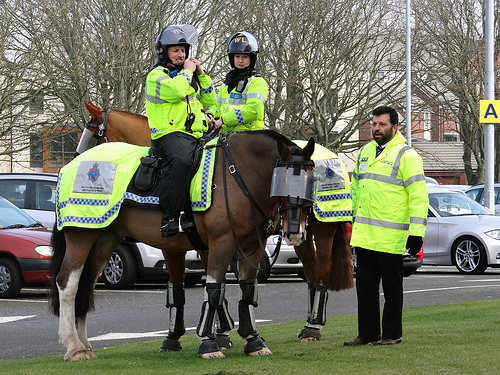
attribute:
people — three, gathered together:
[139, 22, 441, 364]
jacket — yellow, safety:
[136, 63, 221, 148]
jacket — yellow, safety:
[212, 67, 275, 129]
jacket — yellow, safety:
[343, 138, 437, 262]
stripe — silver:
[150, 72, 169, 100]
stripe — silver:
[234, 108, 247, 122]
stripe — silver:
[360, 167, 407, 189]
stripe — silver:
[358, 203, 414, 233]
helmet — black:
[223, 26, 258, 58]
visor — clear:
[159, 22, 198, 43]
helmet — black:
[152, 22, 191, 48]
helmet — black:
[223, 27, 261, 53]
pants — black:
[155, 135, 204, 212]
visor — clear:
[72, 124, 111, 153]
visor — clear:
[268, 163, 320, 203]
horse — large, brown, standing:
[43, 131, 317, 360]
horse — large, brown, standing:
[56, 96, 156, 156]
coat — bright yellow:
[141, 60, 202, 139]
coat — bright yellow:
[347, 141, 430, 259]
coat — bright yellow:
[140, 60, 211, 145]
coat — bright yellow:
[347, 135, 432, 272]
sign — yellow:
[469, 90, 492, 119]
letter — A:
[482, 103, 492, 108]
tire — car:
[444, 234, 491, 283]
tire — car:
[98, 235, 133, 289]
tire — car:
[4, 251, 22, 304]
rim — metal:
[459, 240, 479, 270]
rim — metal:
[104, 250, 123, 279]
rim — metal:
[0, 267, 10, 291]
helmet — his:
[158, 22, 188, 47]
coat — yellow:
[231, 75, 269, 131]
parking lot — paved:
[0, 263, 494, 352]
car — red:
[0, 199, 65, 297]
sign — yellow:
[476, 94, 497, 134]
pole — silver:
[481, 5, 495, 205]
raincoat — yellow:
[349, 138, 429, 256]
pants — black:
[354, 249, 404, 339]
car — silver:
[416, 189, 497, 272]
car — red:
[0, 191, 56, 300]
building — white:
[285, 31, 483, 185]